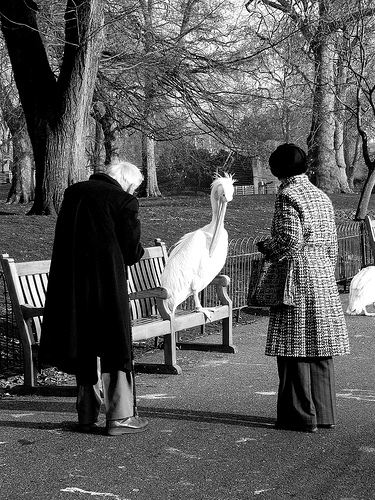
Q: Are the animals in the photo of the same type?
A: Yes, all the animals are birds.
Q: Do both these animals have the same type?
A: Yes, all the animals are birds.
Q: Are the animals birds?
A: Yes, all the animals are birds.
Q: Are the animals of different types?
A: No, all the animals are birds.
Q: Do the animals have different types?
A: No, all the animals are birds.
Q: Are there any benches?
A: Yes, there is a bench.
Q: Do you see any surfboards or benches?
A: Yes, there is a bench.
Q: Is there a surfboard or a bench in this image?
A: Yes, there is a bench.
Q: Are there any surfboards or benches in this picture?
A: Yes, there is a bench.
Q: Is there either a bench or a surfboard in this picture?
A: Yes, there is a bench.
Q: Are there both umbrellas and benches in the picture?
A: No, there is a bench but no umbrellas.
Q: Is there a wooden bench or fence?
A: Yes, there is a wood bench.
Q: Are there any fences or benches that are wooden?
A: Yes, the bench is wooden.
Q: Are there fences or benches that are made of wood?
A: Yes, the bench is made of wood.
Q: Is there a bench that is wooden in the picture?
A: Yes, there is a wood bench.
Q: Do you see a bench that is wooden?
A: Yes, there is a wood bench.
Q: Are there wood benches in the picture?
A: Yes, there is a wood bench.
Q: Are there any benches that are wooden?
A: Yes, there is a bench that is wooden.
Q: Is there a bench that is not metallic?
A: Yes, there is a wooden bench.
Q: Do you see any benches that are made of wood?
A: Yes, there is a bench that is made of wood.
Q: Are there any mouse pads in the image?
A: No, there are no mouse pads.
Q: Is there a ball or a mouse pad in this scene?
A: No, there are no mouse pads or balls.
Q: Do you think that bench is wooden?
A: Yes, the bench is wooden.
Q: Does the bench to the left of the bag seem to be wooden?
A: Yes, the bench is wooden.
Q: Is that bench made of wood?
A: Yes, the bench is made of wood.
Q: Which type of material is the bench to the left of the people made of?
A: The bench is made of wood.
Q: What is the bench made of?
A: The bench is made of wood.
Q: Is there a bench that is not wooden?
A: No, there is a bench but it is wooden.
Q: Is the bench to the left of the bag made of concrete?
A: No, the bench is made of wood.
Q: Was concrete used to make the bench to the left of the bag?
A: No, the bench is made of wood.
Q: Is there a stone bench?
A: No, there is a bench but it is made of wood.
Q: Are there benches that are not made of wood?
A: No, there is a bench but it is made of wood.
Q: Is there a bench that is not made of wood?
A: No, there is a bench but it is made of wood.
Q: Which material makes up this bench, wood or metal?
A: The bench is made of wood.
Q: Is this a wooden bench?
A: Yes, this is a wooden bench.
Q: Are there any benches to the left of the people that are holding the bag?
A: Yes, there is a bench to the left of the people.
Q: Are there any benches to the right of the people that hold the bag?
A: No, the bench is to the left of the people.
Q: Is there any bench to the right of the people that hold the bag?
A: No, the bench is to the left of the people.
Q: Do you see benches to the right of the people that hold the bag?
A: No, the bench is to the left of the people.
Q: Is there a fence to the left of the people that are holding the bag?
A: No, there is a bench to the left of the people.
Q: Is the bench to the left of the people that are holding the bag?
A: Yes, the bench is to the left of the people.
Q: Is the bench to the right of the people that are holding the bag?
A: No, the bench is to the left of the people.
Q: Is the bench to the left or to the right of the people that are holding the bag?
A: The bench is to the left of the people.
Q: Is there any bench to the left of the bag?
A: Yes, there is a bench to the left of the bag.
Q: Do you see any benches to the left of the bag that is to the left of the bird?
A: Yes, there is a bench to the left of the bag.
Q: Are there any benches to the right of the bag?
A: No, the bench is to the left of the bag.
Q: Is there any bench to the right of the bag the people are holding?
A: No, the bench is to the left of the bag.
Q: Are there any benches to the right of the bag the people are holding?
A: No, the bench is to the left of the bag.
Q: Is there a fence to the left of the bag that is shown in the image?
A: No, there is a bench to the left of the bag.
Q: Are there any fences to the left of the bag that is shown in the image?
A: No, there is a bench to the left of the bag.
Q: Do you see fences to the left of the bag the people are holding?
A: No, there is a bench to the left of the bag.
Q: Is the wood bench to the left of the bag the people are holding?
A: Yes, the bench is to the left of the bag.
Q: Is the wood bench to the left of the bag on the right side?
A: Yes, the bench is to the left of the bag.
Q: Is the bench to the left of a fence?
A: No, the bench is to the left of the bag.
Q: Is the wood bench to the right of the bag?
A: No, the bench is to the left of the bag.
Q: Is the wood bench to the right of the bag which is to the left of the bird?
A: No, the bench is to the left of the bag.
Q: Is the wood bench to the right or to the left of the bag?
A: The bench is to the left of the bag.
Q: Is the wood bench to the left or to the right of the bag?
A: The bench is to the left of the bag.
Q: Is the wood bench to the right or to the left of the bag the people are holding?
A: The bench is to the left of the bag.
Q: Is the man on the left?
A: Yes, the man is on the left of the image.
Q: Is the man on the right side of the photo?
A: No, the man is on the left of the image.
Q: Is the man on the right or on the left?
A: The man is on the left of the image.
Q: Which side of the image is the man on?
A: The man is on the left of the image.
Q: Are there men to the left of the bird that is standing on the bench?
A: Yes, there is a man to the left of the bird.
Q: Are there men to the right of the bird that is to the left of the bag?
A: No, the man is to the left of the bird.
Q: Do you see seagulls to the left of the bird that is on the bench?
A: No, there is a man to the left of the bird.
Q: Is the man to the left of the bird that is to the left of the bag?
A: Yes, the man is to the left of the bird.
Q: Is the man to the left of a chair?
A: No, the man is to the left of the bird.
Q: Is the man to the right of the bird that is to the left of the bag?
A: No, the man is to the left of the bird.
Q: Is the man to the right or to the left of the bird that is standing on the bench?
A: The man is to the left of the bird.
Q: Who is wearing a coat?
A: The man is wearing a coat.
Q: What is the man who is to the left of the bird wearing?
A: The man is wearing a coat.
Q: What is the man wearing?
A: The man is wearing a coat.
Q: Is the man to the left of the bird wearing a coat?
A: Yes, the man is wearing a coat.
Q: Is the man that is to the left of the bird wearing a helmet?
A: No, the man is wearing a coat.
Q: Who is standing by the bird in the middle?
A: The man is standing by the bird.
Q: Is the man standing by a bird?
A: Yes, the man is standing by a bird.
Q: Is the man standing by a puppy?
A: No, the man is standing by a bird.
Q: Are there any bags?
A: Yes, there is a bag.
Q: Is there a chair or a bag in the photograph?
A: Yes, there is a bag.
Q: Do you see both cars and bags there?
A: No, there is a bag but no cars.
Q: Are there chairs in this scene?
A: No, there are no chairs.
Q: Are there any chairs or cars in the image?
A: No, there are no chairs or cars.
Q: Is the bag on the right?
A: Yes, the bag is on the right of the image.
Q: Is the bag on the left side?
A: No, the bag is on the right of the image.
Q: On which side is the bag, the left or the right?
A: The bag is on the right of the image.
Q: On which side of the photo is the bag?
A: The bag is on the right of the image.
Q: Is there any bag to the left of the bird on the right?
A: Yes, there is a bag to the left of the bird.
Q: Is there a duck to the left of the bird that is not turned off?
A: No, there is a bag to the left of the bird.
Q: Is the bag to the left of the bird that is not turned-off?
A: Yes, the bag is to the left of the bird.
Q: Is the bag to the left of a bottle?
A: No, the bag is to the left of the bird.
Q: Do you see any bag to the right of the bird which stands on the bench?
A: Yes, there is a bag to the right of the bird.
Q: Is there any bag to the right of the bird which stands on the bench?
A: Yes, there is a bag to the right of the bird.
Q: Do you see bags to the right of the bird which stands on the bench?
A: Yes, there is a bag to the right of the bird.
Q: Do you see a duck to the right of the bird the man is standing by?
A: No, there is a bag to the right of the bird.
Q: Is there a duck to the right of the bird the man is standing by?
A: No, there is a bag to the right of the bird.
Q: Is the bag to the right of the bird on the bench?
A: Yes, the bag is to the right of the bird.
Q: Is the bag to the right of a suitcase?
A: No, the bag is to the right of the bird.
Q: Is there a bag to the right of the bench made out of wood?
A: Yes, there is a bag to the right of the bench.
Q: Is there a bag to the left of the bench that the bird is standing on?
A: No, the bag is to the right of the bench.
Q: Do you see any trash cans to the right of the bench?
A: No, there is a bag to the right of the bench.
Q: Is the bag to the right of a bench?
A: Yes, the bag is to the right of a bench.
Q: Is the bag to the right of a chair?
A: No, the bag is to the right of a bench.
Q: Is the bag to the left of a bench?
A: No, the bag is to the right of a bench.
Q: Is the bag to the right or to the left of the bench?
A: The bag is to the right of the bench.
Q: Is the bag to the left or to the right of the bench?
A: The bag is to the right of the bench.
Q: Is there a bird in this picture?
A: Yes, there is a bird.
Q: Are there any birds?
A: Yes, there is a bird.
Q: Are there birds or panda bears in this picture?
A: Yes, there is a bird.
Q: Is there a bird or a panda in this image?
A: Yes, there is a bird.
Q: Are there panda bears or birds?
A: Yes, there is a bird.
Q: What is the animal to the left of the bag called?
A: The animal is a bird.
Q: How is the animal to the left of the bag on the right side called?
A: The animal is a bird.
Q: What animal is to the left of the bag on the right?
A: The animal is a bird.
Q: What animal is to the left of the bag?
A: The animal is a bird.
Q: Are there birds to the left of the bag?
A: Yes, there is a bird to the left of the bag.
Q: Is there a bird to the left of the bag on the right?
A: Yes, there is a bird to the left of the bag.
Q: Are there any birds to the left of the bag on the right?
A: Yes, there is a bird to the left of the bag.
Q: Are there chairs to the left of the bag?
A: No, there is a bird to the left of the bag.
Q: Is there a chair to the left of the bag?
A: No, there is a bird to the left of the bag.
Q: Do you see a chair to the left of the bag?
A: No, there is a bird to the left of the bag.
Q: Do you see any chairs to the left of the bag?
A: No, there is a bird to the left of the bag.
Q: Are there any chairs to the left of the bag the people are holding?
A: No, there is a bird to the left of the bag.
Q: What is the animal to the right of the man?
A: The animal is a bird.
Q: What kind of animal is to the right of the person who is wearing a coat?
A: The animal is a bird.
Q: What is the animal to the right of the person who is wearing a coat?
A: The animal is a bird.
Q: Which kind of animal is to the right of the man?
A: The animal is a bird.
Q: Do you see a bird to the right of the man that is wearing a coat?
A: Yes, there is a bird to the right of the man.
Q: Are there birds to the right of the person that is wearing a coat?
A: Yes, there is a bird to the right of the man.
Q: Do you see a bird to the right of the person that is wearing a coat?
A: Yes, there is a bird to the right of the man.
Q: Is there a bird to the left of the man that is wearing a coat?
A: No, the bird is to the right of the man.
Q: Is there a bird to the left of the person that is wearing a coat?
A: No, the bird is to the right of the man.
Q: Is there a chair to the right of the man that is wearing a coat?
A: No, there is a bird to the right of the man.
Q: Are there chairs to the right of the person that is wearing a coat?
A: No, there is a bird to the right of the man.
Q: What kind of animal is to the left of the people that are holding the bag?
A: The animal is a bird.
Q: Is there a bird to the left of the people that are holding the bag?
A: Yes, there is a bird to the left of the people.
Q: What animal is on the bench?
A: The bird is on the bench.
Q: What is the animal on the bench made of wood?
A: The animal is a bird.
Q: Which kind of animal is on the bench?
A: The animal is a bird.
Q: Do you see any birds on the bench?
A: Yes, there is a bird on the bench.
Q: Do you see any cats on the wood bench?
A: No, there is a bird on the bench.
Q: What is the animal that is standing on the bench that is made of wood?
A: The animal is a bird.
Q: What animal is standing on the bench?
A: The animal is a bird.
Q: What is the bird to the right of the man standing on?
A: The bird is standing on the bench.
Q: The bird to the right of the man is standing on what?
A: The bird is standing on the bench.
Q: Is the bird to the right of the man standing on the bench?
A: Yes, the bird is standing on the bench.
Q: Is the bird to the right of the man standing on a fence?
A: No, the bird is standing on the bench.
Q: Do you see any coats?
A: Yes, there is a coat.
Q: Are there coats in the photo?
A: Yes, there is a coat.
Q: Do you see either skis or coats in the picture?
A: Yes, there is a coat.